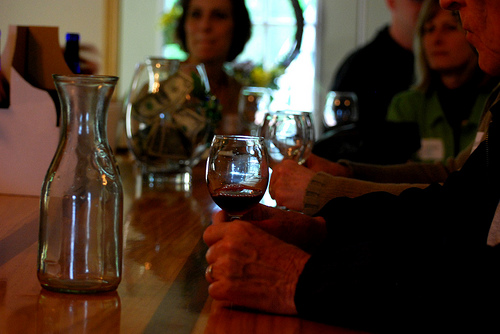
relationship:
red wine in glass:
[210, 188, 262, 213] [202, 140, 271, 225]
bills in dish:
[136, 73, 206, 161] [117, 54, 221, 189]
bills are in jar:
[136, 73, 206, 161] [120, 57, 219, 173]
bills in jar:
[136, 73, 206, 161] [120, 57, 219, 173]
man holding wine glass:
[201, 0, 500, 334] [201, 130, 273, 219]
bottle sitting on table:
[37, 73, 124, 294] [7, 188, 337, 332]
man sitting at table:
[201, 0, 500, 334] [4, 147, 498, 317]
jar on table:
[120, 57, 219, 173] [7, 140, 451, 331]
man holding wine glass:
[201, 0, 500, 334] [200, 131, 268, 224]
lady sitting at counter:
[164, 3, 256, 153] [0, 161, 351, 334]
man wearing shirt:
[197, 5, 496, 332] [303, 119, 498, 331]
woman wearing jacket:
[388, 3, 494, 158] [383, 80, 494, 162]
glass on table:
[200, 130, 269, 223] [4, 147, 498, 317]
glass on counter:
[260, 110, 313, 169] [0, 161, 351, 334]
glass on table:
[297, 107, 315, 165] [4, 147, 498, 317]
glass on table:
[317, 84, 362, 128] [3, 128, 493, 327]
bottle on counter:
[37, 73, 124, 294] [0, 161, 351, 334]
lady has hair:
[164, 3, 256, 153] [231, 3, 252, 53]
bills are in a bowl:
[136, 60, 206, 170] [108, 52, 224, 202]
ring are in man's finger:
[197, 260, 218, 285] [197, 252, 246, 286]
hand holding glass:
[256, 149, 337, 212] [205, 134, 269, 220]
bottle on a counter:
[34, 64, 126, 298] [0, 161, 351, 334]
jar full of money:
[120, 57, 219, 173] [128, 58, 214, 175]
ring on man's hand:
[197, 260, 218, 285] [196, 257, 253, 287]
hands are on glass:
[197, 216, 306, 327] [195, 121, 269, 226]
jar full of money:
[120, 57, 219, 173] [131, 67, 214, 177]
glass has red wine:
[205, 134, 269, 220] [210, 182, 260, 215]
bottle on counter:
[37, 73, 124, 294] [2, 189, 303, 332]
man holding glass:
[201, 0, 500, 334] [205, 134, 269, 220]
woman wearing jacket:
[388, 0, 493, 158] [383, 80, 494, 180]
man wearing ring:
[197, 5, 496, 332] [206, 263, 217, 282]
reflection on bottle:
[63, 180, 96, 287] [37, 73, 124, 294]